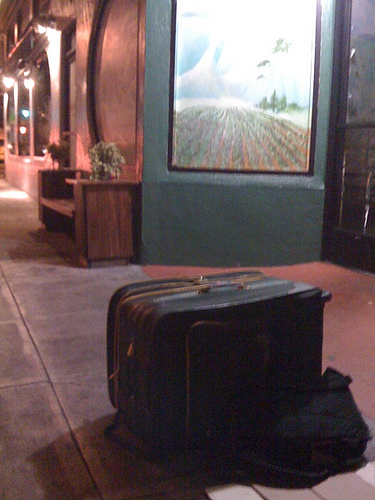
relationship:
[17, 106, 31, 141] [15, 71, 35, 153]
reflection in window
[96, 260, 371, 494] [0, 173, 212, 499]
luggage on sidewalk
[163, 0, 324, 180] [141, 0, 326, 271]
poster on wall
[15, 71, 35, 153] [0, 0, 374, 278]
window on building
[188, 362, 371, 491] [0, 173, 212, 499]
backpack on sidewalk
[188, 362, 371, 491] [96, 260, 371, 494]
backpack behind luggage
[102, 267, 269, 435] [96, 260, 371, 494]
trim on luggage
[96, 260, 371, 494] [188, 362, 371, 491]
luggage near backpack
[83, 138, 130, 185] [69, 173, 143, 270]
plant on arm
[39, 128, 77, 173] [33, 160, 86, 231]
plant on arm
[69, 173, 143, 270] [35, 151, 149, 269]
arm on bench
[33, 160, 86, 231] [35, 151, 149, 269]
arm on bench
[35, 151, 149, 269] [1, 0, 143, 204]
bench near wall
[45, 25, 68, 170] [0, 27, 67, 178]
column in row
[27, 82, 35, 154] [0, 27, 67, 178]
column in row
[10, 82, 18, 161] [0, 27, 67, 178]
column in row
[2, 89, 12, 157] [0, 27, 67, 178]
column in row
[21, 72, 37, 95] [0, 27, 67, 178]
light in row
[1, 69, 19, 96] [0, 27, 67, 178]
light in row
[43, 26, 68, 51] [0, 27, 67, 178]
light in row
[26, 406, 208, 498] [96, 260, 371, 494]
shadow near luggage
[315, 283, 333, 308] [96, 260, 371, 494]
wheels on luggage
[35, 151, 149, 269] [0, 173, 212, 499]
bench on sidewalk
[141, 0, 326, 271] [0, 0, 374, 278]
wall on building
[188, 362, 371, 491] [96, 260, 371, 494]
backpack near luggage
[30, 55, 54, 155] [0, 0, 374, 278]
window on building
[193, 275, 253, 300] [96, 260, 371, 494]
handle on luggage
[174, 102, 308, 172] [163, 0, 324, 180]
plants on poster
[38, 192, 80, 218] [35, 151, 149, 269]
seat on bench